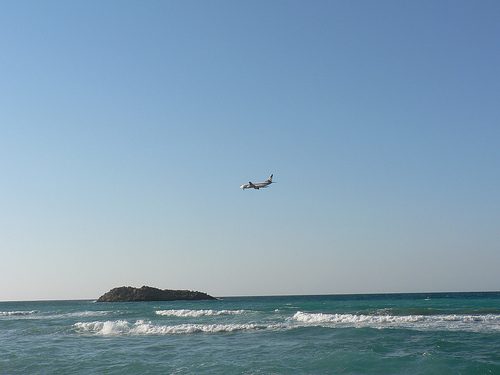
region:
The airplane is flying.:
[229, 160, 286, 207]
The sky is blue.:
[119, 41, 296, 124]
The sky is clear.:
[64, 41, 215, 133]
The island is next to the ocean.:
[94, 276, 228, 316]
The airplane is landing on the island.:
[92, 170, 306, 320]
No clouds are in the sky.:
[94, 38, 262, 122]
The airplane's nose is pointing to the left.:
[234, 165, 288, 199]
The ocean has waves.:
[87, 302, 428, 363]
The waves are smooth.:
[65, 296, 292, 340]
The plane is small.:
[232, 168, 282, 198]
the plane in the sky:
[227, 168, 293, 200]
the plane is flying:
[238, 163, 282, 195]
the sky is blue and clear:
[15, 9, 395, 120]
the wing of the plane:
[242, 178, 258, 188]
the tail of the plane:
[262, 173, 281, 188]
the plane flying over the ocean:
[230, 165, 286, 192]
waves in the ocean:
[99, 293, 491, 365]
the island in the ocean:
[91, 283, 226, 309]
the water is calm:
[225, 295, 488, 360]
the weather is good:
[10, 10, 499, 365]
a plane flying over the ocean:
[162, 141, 343, 334]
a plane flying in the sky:
[218, 157, 298, 234]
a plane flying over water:
[216, 143, 301, 353]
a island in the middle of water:
[82, 260, 229, 336]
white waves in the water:
[245, 300, 465, 359]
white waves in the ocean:
[145, 301, 460, 353]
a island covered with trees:
[82, 277, 209, 323]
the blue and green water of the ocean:
[247, 274, 489, 371]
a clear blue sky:
[75, 68, 363, 164]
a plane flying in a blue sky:
[188, 131, 361, 235]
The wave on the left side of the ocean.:
[1, 302, 36, 316]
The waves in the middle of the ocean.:
[68, 307, 272, 340]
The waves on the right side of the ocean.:
[285, 300, 496, 340]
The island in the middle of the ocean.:
[90, 280, 215, 298]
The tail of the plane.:
[268, 173, 273, 180]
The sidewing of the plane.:
[246, 178, 256, 188]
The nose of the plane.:
[241, 185, 245, 187]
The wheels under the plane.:
[248, 186, 258, 188]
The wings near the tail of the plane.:
[264, 179, 279, 182]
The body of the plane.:
[241, 180, 266, 187]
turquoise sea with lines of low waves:
[2, 293, 494, 369]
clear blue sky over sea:
[0, 5, 492, 296]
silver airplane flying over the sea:
[232, 166, 273, 346]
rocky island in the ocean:
[95, 281, 217, 301]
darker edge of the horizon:
[207, 291, 487, 298]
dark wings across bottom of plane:
[240, 166, 275, 191]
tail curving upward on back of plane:
[240, 166, 275, 191]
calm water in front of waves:
[76, 320, 416, 366]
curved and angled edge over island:
[95, 280, 215, 305]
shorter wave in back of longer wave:
[72, 301, 275, 337]